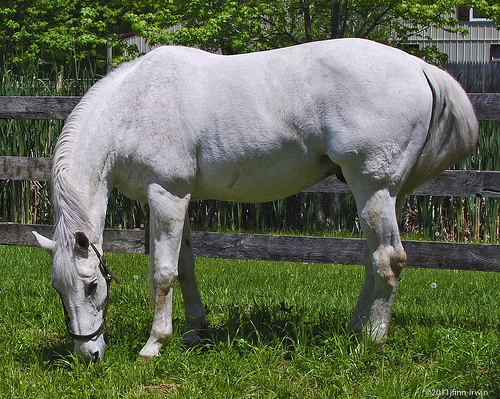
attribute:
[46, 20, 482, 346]
horse — eating, white, present, eaing, here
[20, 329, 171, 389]
grass — tall, green, cut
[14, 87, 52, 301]
fence — old, wooden, pointy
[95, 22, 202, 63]
tree — green, leafy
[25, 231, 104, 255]
ears — pointy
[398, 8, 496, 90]
building — tan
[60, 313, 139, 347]
halter — leather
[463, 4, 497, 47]
window — here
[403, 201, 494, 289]
field — here